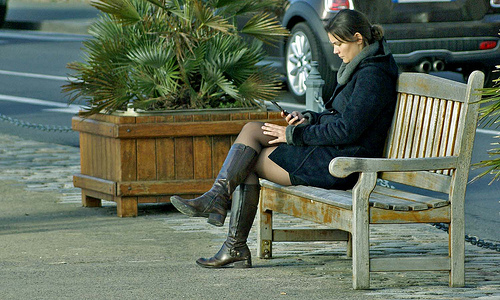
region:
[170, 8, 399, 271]
a woman viewing her cell phone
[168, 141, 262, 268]
a woman wearing black boots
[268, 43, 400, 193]
a woman wearing a blue coat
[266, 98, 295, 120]
a woman holding cell phone in her right hand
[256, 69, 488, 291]
woman is sitting in old wooden chair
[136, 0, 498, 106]
black vehicle park near side walk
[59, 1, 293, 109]
a beautiful green plant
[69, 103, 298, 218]
a wooden plant box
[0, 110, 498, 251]
chain in front of road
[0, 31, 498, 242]
road with three white lines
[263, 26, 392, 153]
this is a lady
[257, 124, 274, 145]
the lady is light skinned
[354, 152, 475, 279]
this is a bench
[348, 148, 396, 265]
the bench is wooden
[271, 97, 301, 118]
this is a phone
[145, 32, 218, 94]
this is a tree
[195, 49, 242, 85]
the leaves are green in color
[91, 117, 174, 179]
this is a box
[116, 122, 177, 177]
the box is brown in color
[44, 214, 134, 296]
this is the ground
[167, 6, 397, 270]
A woman sitting down.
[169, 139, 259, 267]
A pair of brown boots.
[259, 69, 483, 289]
A gray colored bench.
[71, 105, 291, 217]
A large wooden planter.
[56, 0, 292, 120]
A green palm plant.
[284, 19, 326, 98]
A vehicle tire.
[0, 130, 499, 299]
An area of sidewalk.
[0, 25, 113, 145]
An area of paved roadway.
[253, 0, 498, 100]
A dark colored vehicle.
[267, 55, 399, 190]
A black colored coat.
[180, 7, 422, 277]
this is a person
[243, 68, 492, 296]
this is a bench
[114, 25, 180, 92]
this is a leaf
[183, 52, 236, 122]
this is a leaf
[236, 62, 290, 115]
this is a leaf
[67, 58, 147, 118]
this is a leaf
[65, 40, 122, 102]
this is a leaf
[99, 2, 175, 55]
this is a leaf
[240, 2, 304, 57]
this is a leaf